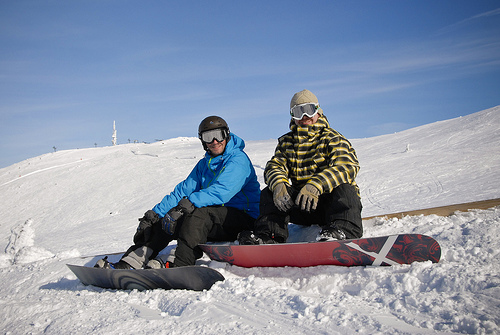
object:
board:
[64, 264, 225, 292]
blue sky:
[2, 2, 498, 98]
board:
[198, 233, 441, 269]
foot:
[93, 256, 137, 270]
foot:
[145, 259, 176, 270]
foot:
[238, 230, 281, 246]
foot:
[316, 230, 347, 241]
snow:
[395, 122, 442, 172]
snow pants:
[120, 205, 257, 267]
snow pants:
[253, 182, 364, 243]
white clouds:
[280, 34, 499, 89]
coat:
[263, 114, 361, 198]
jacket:
[151, 132, 262, 221]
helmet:
[198, 115, 232, 150]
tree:
[110, 117, 117, 145]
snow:
[221, 270, 486, 334]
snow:
[17, 165, 128, 242]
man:
[237, 89, 363, 246]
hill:
[1, 104, 500, 335]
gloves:
[133, 197, 196, 245]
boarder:
[93, 114, 261, 278]